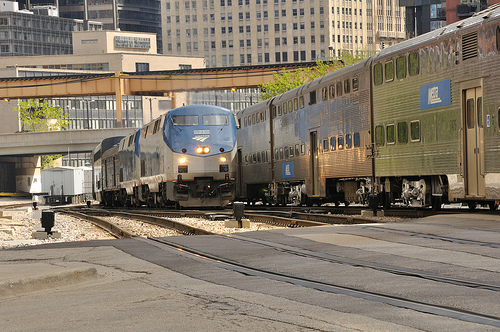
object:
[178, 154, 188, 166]
lights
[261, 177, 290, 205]
wheels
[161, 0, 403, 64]
apartment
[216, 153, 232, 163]
lights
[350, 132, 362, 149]
screen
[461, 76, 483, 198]
door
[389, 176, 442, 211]
wheels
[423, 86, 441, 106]
logo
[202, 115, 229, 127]
windows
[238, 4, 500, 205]
trains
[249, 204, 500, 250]
track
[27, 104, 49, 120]
leaves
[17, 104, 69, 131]
trees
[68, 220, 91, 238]
gravel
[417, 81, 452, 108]
sign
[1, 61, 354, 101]
tracks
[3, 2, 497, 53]
background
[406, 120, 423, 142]
windows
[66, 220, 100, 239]
pebbles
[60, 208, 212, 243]
track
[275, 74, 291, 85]
leaves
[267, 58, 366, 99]
trees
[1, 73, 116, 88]
wires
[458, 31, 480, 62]
vent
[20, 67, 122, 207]
building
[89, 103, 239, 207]
train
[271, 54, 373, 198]
cars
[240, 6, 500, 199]
side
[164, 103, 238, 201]
front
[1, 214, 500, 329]
road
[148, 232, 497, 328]
tracks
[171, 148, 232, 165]
four lights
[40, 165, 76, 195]
back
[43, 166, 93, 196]
truck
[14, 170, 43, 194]
white back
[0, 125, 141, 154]
bridge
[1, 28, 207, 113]
industrial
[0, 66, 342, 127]
background